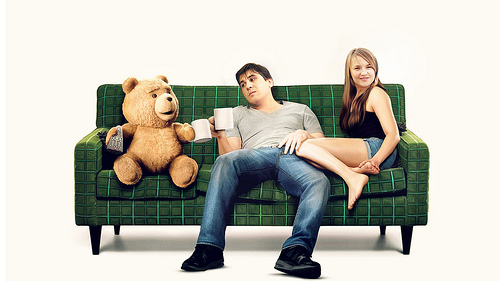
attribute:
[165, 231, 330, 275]
shoes — black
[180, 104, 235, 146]
mugs — white, for coffee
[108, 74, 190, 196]
bear — a teddy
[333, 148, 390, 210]
feet — bare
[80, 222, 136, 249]
legs — wooden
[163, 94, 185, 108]
nose — black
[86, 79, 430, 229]
sofa — green, stripes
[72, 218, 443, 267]
legs — black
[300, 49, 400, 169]
girl — barefoot, sitting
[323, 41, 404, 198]
girl — long haired, brown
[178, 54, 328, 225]
boy — lounging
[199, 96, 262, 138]
cup — white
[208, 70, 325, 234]
boy — brown haired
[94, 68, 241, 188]
ted — sitting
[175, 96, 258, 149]
mugs — clinking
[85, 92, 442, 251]
couch — green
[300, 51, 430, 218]
woman — blonde, sleeveless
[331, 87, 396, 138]
shirt — black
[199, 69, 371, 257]
man — brown haired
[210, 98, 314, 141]
tshirt — gray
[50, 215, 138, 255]
legs — brown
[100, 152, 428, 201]
pillows — plaid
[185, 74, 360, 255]
man — sitting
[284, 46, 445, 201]
girl — sitting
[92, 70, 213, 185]
bear — sitting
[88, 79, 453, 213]
couch — green, plaid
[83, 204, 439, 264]
legs — wooden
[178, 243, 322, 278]
shoes — black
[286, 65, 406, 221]
girl — barefoot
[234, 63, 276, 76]
hair — dark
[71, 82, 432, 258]
couch — green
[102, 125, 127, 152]
control — remote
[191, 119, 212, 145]
mug — white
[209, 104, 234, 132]
mug — white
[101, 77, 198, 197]
bear — brown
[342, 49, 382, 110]
hair — long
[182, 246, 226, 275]
shoe — black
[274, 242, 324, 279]
shoe — black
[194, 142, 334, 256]
jeans — blue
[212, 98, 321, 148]
shirt — gray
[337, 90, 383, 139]
shirt — black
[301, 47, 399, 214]
girl — smiling